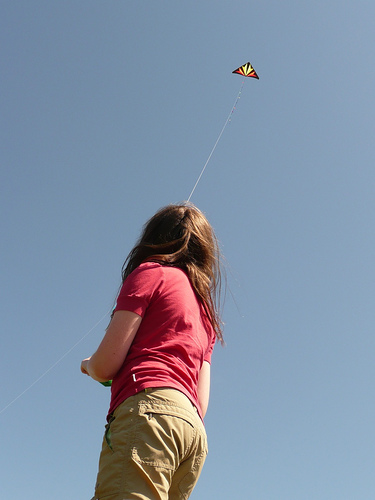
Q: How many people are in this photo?
A: One.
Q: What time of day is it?
A: Daytime.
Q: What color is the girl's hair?
A: Brown.